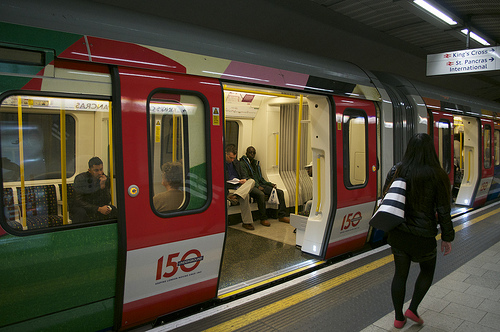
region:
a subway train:
[0, 16, 497, 331]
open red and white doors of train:
[119, 77, 384, 316]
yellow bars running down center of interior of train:
[4, 93, 307, 233]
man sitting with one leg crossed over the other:
[219, 143, 256, 230]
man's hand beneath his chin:
[68, 153, 114, 198]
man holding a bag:
[263, 179, 280, 209]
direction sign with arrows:
[422, 22, 499, 76]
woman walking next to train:
[236, 110, 470, 330]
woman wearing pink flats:
[391, 307, 425, 328]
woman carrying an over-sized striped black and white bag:
[369, 158, 409, 237]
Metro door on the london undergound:
[113, 64, 233, 330]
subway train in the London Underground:
[11, 26, 498, 330]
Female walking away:
[373, 129, 456, 328]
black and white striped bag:
[367, 176, 409, 238]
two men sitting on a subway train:
[224, 142, 292, 230]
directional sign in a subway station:
[418, 46, 498, 76]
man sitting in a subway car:
[68, 155, 118, 227]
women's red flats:
[387, 303, 424, 330]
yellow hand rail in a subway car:
[288, 97, 308, 249]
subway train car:
[401, 88, 497, 210]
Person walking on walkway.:
[346, 133, 456, 321]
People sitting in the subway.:
[211, 138, 291, 209]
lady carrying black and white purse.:
[390, 158, 416, 235]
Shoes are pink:
[383, 305, 430, 330]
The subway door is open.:
[170, 87, 342, 260]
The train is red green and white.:
[101, 77, 359, 248]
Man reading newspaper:
[223, 160, 252, 196]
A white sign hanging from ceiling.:
[419, 33, 498, 83]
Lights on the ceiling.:
[401, 2, 484, 47]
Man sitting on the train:
[68, 138, 110, 218]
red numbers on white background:
[146, 251, 197, 284]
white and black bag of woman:
[363, 179, 405, 239]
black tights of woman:
[389, 255, 431, 305]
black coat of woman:
[384, 165, 451, 243]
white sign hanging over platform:
[426, 47, 498, 77]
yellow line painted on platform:
[206, 202, 496, 329]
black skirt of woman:
[388, 228, 432, 260]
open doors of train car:
[120, 74, 385, 326]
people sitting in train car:
[68, 137, 291, 223]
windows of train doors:
[144, 92, 374, 216]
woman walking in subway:
[362, 125, 457, 330]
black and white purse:
[380, 170, 403, 225]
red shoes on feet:
[380, 294, 425, 328]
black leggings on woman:
[374, 248, 448, 328]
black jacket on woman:
[377, 158, 468, 231]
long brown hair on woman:
[400, 128, 440, 186]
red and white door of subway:
[82, 74, 237, 319]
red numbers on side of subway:
[117, 243, 214, 306]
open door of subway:
[172, 63, 360, 296]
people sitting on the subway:
[66, 143, 299, 239]